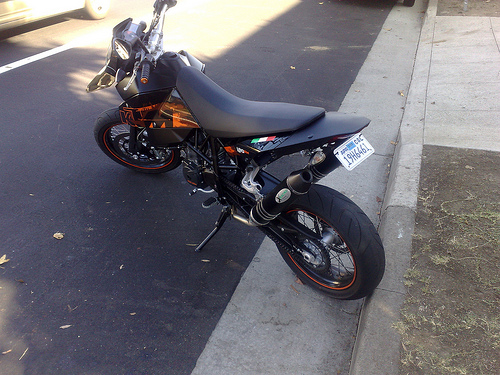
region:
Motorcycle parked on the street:
[79, 0, 391, 314]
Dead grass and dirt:
[400, 145, 497, 372]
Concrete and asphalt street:
[18, 272, 318, 364]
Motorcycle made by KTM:
[82, 1, 382, 302]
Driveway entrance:
[368, 12, 495, 141]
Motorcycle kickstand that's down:
[177, 188, 242, 268]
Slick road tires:
[249, 167, 391, 312]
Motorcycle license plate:
[327, 120, 391, 180]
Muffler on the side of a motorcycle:
[230, 155, 318, 235]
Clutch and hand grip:
[120, 50, 160, 95]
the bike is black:
[57, 12, 422, 307]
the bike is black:
[72, 8, 370, 267]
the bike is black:
[43, 25, 402, 272]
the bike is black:
[80, 45, 420, 263]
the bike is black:
[109, 65, 351, 235]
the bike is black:
[100, 22, 430, 240]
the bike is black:
[45, 43, 362, 233]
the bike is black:
[74, 17, 332, 235]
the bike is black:
[93, 56, 352, 267]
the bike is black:
[38, 24, 418, 255]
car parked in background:
[1, 0, 118, 28]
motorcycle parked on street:
[75, 0, 406, 304]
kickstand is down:
[186, 191, 245, 270]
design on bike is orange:
[110, 86, 210, 153]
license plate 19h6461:
[327, 125, 389, 177]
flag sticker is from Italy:
[247, 125, 287, 152]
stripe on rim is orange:
[260, 176, 388, 308]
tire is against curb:
[268, 160, 403, 319]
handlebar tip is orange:
[128, 48, 164, 93]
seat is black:
[164, 40, 335, 162]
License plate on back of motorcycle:
[328, 130, 374, 170]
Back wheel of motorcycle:
[267, 183, 387, 299]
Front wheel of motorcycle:
[91, 105, 187, 173]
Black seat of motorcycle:
[183, 62, 323, 133]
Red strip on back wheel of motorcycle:
[270, 230, 360, 291]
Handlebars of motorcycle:
[115, 0, 176, 100]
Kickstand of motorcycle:
[185, 217, 221, 254]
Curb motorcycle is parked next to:
[350, 0, 438, 372]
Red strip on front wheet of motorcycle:
[96, 102, 184, 173]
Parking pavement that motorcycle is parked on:
[0, 3, 424, 369]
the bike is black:
[73, 25, 308, 213]